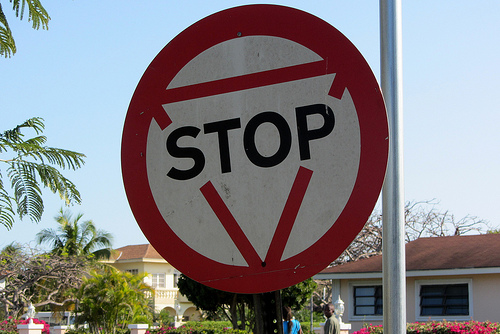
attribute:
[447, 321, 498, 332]
flowers — pink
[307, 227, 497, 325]
home — beige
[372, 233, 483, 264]
roof — red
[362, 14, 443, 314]
pole — silver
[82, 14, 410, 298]
sign — red with white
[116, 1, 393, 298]
sign — Red, white and black, round, stop sign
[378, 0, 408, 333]
pole — tall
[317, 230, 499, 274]
roof — Brown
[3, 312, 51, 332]
flowers — colorful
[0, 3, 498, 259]
clear day —  sunny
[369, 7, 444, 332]
pole —  Silver, metal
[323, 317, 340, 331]
top — green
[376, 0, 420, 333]
pole — Metal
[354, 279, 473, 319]
windows — open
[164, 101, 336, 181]
word — stop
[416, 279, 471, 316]
window — black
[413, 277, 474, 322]
trim — white